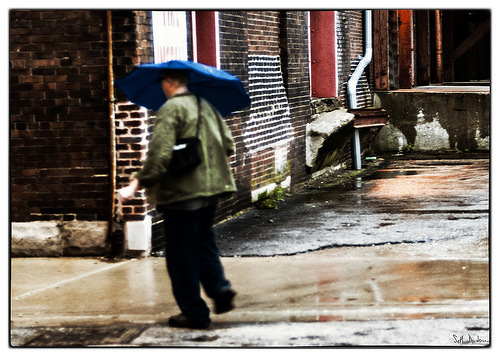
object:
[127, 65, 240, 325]
woman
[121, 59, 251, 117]
umbrella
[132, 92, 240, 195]
jacket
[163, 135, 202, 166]
purse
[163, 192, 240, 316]
pants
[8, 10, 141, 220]
wall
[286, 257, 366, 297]
sidewalk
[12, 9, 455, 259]
building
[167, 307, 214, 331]
shoe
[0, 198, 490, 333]
ground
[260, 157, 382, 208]
plant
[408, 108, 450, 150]
patch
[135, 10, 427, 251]
wall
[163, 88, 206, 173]
bag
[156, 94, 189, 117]
shoulder